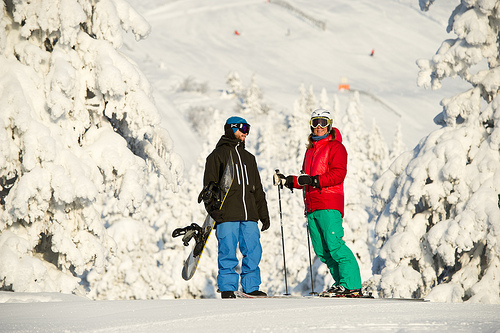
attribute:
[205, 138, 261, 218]
sweater — black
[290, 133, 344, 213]
coat — red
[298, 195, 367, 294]
pants — green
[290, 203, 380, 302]
pants — green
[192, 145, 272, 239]
coat — brown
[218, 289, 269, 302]
boots — black 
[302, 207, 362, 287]
pants — green 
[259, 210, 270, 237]
gloves — black 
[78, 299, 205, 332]
snow — white, thick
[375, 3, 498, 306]
tree — tall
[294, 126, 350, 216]
jacket — red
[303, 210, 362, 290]
trouser — green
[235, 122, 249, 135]
goggles — snow, black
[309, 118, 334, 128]
goggles — snow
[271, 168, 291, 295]
ski pole — black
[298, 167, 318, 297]
ski pole — black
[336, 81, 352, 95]
sign — orange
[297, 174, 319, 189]
glove — black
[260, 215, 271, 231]
glove — black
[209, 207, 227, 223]
glove — black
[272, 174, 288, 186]
glove — black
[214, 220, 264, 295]
pants — blue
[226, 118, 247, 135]
hat — blue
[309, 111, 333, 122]
hat — white 